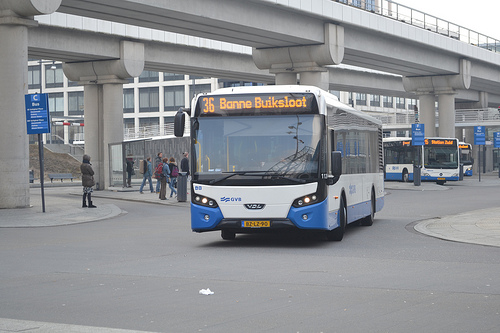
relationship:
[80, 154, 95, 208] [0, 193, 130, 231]
woman standing on sidewalk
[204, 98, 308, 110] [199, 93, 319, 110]
print on background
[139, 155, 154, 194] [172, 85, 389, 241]
person walking near bus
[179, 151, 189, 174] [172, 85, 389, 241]
person walking near bus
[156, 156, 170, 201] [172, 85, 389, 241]
person walking near bus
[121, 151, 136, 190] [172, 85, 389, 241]
person walking near bus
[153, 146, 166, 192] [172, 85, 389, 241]
person walking near bus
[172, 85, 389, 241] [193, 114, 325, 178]
bus has windshield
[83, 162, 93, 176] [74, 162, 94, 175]
woman wears jacket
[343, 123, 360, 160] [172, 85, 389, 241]
window on bus